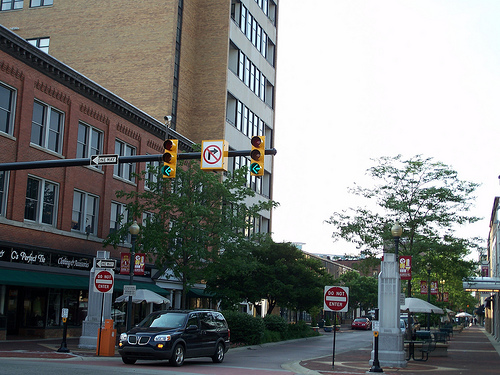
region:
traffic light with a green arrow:
[251, 135, 272, 178]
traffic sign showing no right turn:
[193, 135, 233, 180]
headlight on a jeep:
[154, 330, 174, 350]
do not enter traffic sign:
[316, 278, 348, 315]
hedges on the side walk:
[219, 301, 265, 346]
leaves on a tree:
[230, 226, 330, 303]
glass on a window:
[18, 168, 65, 225]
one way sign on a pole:
[86, 151, 126, 171]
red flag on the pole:
[394, 252, 411, 284]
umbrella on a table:
[394, 288, 449, 361]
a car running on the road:
[113, 294, 238, 367]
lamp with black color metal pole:
[387, 223, 405, 255]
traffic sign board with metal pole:
[91, 268, 114, 354]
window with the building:
[6, 93, 140, 232]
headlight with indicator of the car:
[113, 332, 175, 352]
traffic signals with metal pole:
[91, 135, 274, 185]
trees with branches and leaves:
[166, 178, 291, 299]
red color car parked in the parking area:
[352, 314, 367, 331]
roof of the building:
[21, 26, 166, 117]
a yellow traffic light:
[247, 131, 270, 179]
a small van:
[117, 305, 234, 370]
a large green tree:
[204, 240, 325, 320]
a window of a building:
[26, 98, 48, 145]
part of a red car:
[347, 313, 372, 333]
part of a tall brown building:
[1, 0, 286, 235]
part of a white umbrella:
[396, 288, 439, 317]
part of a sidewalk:
[437, 316, 495, 371]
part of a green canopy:
[0, 266, 83, 293]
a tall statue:
[370, 249, 411, 364]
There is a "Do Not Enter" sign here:
[331, 275, 364, 328]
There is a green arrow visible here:
[244, 155, 268, 187]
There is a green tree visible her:
[391, 165, 429, 215]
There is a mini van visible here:
[173, 306, 229, 369]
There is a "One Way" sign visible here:
[88, 153, 125, 189]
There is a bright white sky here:
[306, 140, 321, 185]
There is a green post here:
[368, 344, 387, 366]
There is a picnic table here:
[415, 331, 423, 356]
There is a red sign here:
[397, 254, 416, 321]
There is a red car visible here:
[356, 312, 368, 371]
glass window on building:
[29, 97, 45, 147]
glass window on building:
[1, 80, 13, 137]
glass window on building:
[49, 107, 61, 152]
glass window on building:
[78, 120, 88, 161]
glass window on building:
[91, 128, 103, 166]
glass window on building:
[113, 138, 120, 175]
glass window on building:
[124, 145, 132, 182]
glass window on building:
[24, 174, 39, 224]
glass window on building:
[43, 181, 56, 222]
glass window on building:
[72, 188, 83, 230]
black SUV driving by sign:
[106, 288, 240, 360]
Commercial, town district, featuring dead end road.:
[2, 1, 498, 373]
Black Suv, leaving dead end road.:
[123, 306, 227, 365]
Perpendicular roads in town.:
[6, 326, 373, 372]